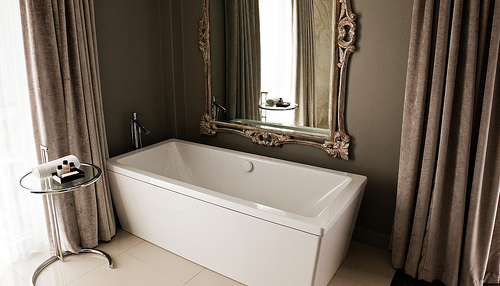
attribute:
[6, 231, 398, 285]
tiles — light colored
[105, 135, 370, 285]
white bathtub — is white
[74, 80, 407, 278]
bathtub — is small, is white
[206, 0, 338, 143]
mirror — is large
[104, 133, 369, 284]
bathtub — white, large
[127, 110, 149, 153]
fixture — water, faucet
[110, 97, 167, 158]
fixture — is small, is silver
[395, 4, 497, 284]
curtain — is long, is tan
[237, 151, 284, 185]
drain — upper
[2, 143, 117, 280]
table — Small, glass, chrome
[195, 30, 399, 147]
frame — Golden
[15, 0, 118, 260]
curtain — is sand colored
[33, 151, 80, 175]
towel — small, white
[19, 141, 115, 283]
table — Metal, glass, small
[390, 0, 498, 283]
drape — long, brown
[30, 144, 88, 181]
towel — white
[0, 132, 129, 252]
table — glass surfaced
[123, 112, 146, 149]
fixture — is metal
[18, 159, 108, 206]
glass top — round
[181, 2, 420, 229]
walls — olive, green, painted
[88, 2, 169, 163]
walls — painted, green, olive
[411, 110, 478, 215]
drape — are long, are brown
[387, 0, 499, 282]
curtain — bath 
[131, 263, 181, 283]
tiling — Floor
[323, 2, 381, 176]
frame — decorative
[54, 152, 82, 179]
objects — are small